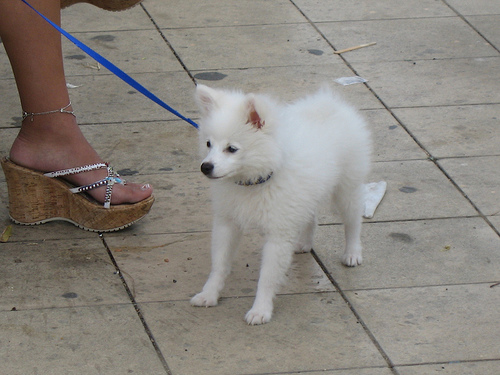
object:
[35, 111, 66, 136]
ankle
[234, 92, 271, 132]
ear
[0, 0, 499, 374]
ground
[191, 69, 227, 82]
spot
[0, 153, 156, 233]
sandal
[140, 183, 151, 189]
toenail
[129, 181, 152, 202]
toe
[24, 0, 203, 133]
blue leash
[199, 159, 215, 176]
nose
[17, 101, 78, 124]
ankle bracelet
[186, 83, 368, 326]
dog